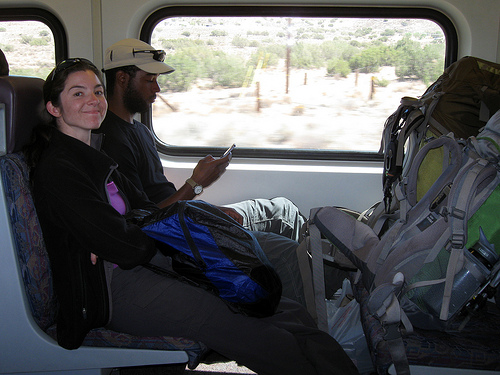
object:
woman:
[28, 57, 361, 374]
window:
[137, 2, 461, 164]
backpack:
[361, 140, 500, 331]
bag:
[131, 198, 281, 317]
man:
[102, 35, 307, 296]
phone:
[220, 144, 238, 159]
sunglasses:
[134, 46, 166, 62]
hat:
[100, 37, 177, 75]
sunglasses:
[52, 57, 98, 81]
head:
[40, 57, 109, 131]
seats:
[0, 77, 203, 371]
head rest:
[2, 75, 56, 153]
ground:
[0, 15, 453, 151]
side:
[1, 0, 499, 209]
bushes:
[319, 57, 355, 80]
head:
[101, 36, 162, 119]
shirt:
[33, 135, 165, 328]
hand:
[188, 148, 232, 192]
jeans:
[219, 197, 309, 291]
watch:
[184, 178, 204, 195]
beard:
[120, 83, 150, 114]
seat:
[354, 279, 499, 373]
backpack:
[410, 53, 497, 145]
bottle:
[423, 235, 500, 323]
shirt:
[98, 111, 185, 210]